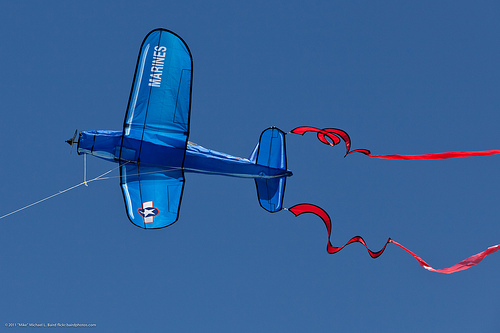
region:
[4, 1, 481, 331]
a scene outside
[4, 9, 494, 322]
a scene happening during the day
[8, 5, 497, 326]
a sky with no clouds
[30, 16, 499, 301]
a blue kite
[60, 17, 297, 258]
a kite in the shape of an airplane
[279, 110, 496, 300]
some red streamers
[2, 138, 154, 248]
a white string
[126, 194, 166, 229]
a white star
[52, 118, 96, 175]
a black propeller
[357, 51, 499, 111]
a blue sky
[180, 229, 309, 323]
the sky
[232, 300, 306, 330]
the sky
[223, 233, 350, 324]
the sky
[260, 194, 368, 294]
the sky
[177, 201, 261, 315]
the sky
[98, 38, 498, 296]
kite in the sky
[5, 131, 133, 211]
string to the kite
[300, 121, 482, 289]
red streamers on the back of kite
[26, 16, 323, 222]
kite is a blue airplane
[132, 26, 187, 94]
MARINES written on the kite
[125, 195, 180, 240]
white star in a blue circle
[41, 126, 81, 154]
propeller on the kite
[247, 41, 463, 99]
sky is clear blue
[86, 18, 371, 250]
kite is outlined in black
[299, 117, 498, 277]
two red streamers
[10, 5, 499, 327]
blue kite shaped like a plane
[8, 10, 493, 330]
blue and red kite in the sky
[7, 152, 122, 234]
white kite string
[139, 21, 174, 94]
white MARINES logo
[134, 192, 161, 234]
red, white, and blue star design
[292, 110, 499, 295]
long red kite streamers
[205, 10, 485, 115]
bright blue sky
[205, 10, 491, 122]
sunny cloudless afternoon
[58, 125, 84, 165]
small airplane propeller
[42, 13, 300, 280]
light blue kite with black trim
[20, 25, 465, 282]
airplane flying in the sky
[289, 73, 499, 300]
red ribbon behind the airplane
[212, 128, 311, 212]
back wing of the aircraft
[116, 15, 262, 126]
marines logo on the side of the wing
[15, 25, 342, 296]
kite flying in the wind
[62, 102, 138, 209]
propeller of the aircraft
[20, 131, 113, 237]
string attaching the kite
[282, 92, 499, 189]
red ribbon behind the aircraft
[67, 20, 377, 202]
marines replica kite flying in the wind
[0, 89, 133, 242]
white string attaching to the nose of the kite